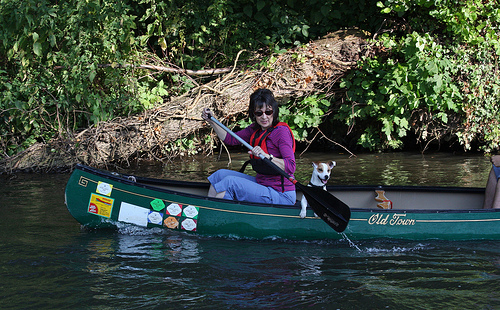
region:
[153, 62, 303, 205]
this is a woman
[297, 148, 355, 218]
this is a dog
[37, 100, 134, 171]
the bark of a tree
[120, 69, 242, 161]
the bark of a tree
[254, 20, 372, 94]
the bark of a tree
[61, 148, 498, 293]
this is a boat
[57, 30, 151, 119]
this is a branch of a tree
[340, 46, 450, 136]
this is a branch of a tree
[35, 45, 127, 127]
this is a branch of a tree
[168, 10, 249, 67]
this is a branch of a tree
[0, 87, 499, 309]
woman canoeing on a river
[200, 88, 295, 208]
woman sitting in canoe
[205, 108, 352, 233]
woman holding black and grey paddle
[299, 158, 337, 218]
dog sitting in canoe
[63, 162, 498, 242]
canoe is green and black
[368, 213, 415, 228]
gold writing on canoe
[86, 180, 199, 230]
multi-colored stickers on canoe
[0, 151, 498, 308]
river is dark and flat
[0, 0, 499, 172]
fallen tree in river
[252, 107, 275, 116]
woman wearing dark sunglasses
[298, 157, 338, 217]
white and brown dog in the canoe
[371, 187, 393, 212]
brown seat in the canoe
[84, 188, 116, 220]
yellow and red sticker on the canoe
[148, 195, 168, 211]
green sticker on the canoe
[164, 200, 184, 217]
white and red sticker on the canoe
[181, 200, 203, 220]
green and white sticker on the canoe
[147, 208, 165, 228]
white and blue sticker on the canoe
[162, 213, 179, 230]
orange sticker on the canoe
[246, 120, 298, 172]
red life jacket on the woman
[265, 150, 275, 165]
watch on the woman's wrist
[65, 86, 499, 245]
Woman riding in a canoe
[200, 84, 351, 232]
Woman using a paddle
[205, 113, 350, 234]
Black paddle with a metal handle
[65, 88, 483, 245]
Woman and a dog riding in a canoe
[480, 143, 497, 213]
Person sitting in the back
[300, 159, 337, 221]
White dog panting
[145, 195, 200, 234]
Six stickers on the side of a canoe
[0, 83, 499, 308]
People and animal canoeing in a river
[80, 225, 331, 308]
Reflection of a canoe on the water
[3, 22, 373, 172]
Fallen tree trunk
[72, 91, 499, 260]
a woman and her dog are in a green canoe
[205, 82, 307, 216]
the woman wears a purple shirt and a red life vest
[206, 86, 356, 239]
the woman paddles with a silver and black oar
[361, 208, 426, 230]
"Old Town" is written in gold on the side of the canoe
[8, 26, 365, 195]
a fallen tree is on the bank behind the woman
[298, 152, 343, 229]
the dog has a brown patch over his eye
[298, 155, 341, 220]
the dog's paws are over the rim of the canoe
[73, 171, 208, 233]
stickers on the front side of the boat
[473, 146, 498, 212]
the man in the back of the canoe is barely visible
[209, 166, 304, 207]
the woman wears blue capri pants